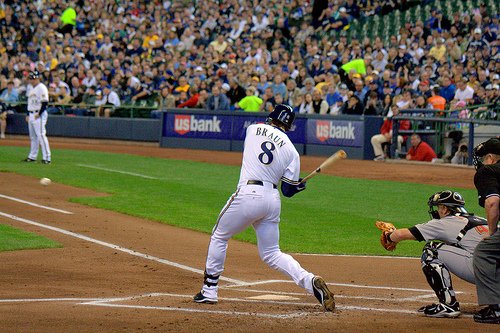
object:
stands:
[0, 0, 495, 116]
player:
[194, 103, 337, 310]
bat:
[298, 149, 349, 187]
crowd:
[8, 1, 499, 107]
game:
[0, 118, 500, 320]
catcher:
[374, 188, 495, 316]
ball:
[37, 177, 54, 187]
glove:
[374, 221, 398, 252]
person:
[239, 87, 264, 110]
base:
[245, 291, 300, 301]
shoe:
[191, 291, 218, 303]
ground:
[82, 287, 498, 332]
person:
[211, 34, 227, 54]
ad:
[163, 115, 229, 137]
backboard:
[64, 104, 158, 143]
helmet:
[268, 104, 296, 128]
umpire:
[470, 134, 498, 323]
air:
[68, 138, 90, 148]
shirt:
[239, 95, 261, 111]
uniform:
[26, 87, 52, 162]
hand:
[298, 180, 305, 190]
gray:
[421, 217, 494, 277]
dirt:
[2, 253, 113, 292]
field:
[1, 135, 498, 330]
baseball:
[39, 176, 51, 189]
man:
[407, 134, 434, 163]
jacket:
[407, 144, 437, 158]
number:
[257, 141, 276, 166]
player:
[25, 71, 53, 165]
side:
[0, 1, 61, 322]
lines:
[81, 303, 317, 321]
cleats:
[322, 285, 335, 308]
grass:
[120, 174, 212, 210]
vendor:
[338, 56, 373, 85]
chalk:
[1, 284, 181, 313]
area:
[310, 3, 499, 64]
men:
[370, 110, 410, 160]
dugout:
[370, 106, 500, 166]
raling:
[391, 109, 499, 161]